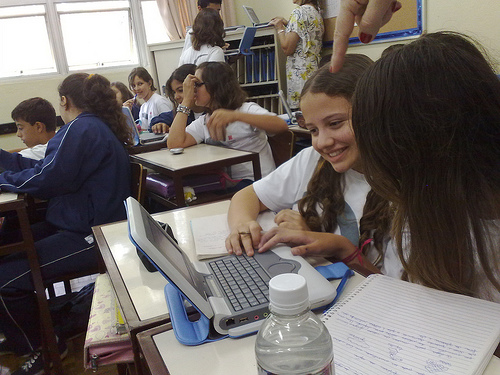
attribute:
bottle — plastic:
[255, 273, 340, 374]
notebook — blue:
[317, 272, 499, 374]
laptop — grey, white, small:
[123, 195, 341, 338]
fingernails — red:
[358, 33, 373, 44]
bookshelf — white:
[229, 27, 286, 116]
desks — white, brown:
[0, 145, 452, 375]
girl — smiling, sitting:
[224, 52, 416, 279]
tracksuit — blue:
[0, 115, 131, 356]